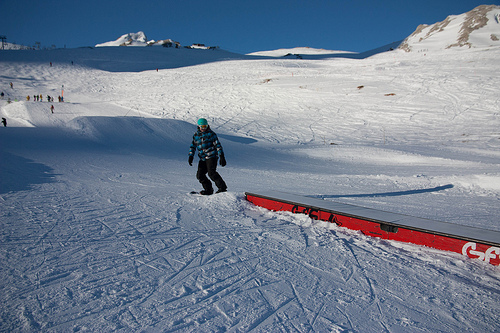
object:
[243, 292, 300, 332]
lines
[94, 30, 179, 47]
snow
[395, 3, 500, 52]
mound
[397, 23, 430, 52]
bare streaks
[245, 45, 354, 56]
mountain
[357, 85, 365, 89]
spot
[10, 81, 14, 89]
people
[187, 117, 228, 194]
man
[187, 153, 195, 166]
glove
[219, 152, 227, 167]
glove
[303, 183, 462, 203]
shadow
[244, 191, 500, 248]
edge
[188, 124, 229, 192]
clothes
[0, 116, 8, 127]
people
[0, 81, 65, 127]
crowd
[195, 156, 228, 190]
pants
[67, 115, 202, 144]
jumps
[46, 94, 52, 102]
snowboarders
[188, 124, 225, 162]
coat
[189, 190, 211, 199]
snowboard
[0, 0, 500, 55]
sky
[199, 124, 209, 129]
goggles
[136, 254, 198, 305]
tracks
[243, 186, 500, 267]
ramp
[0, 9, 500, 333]
snow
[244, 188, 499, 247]
surface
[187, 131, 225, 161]
plaid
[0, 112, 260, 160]
shadow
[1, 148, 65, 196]
shadow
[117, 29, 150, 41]
mountaintops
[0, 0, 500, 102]
distance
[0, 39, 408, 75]
shadow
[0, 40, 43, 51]
mountain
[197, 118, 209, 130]
aqua cap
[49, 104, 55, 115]
people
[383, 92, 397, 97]
earth patches